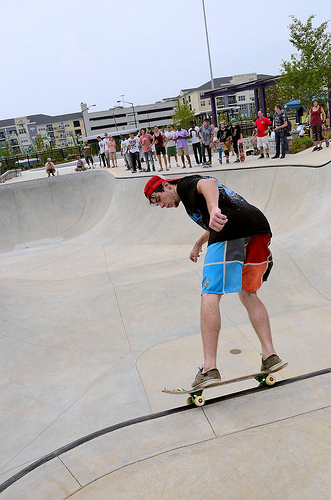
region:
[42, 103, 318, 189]
many people watching skateboarder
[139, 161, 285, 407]
man skateboarding at skateboard park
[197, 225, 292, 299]
man wearing shorts with a square pattern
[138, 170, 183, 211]
man wearing a red baseball cap baskwards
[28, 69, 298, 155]
buildings in the background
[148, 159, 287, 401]
skateboarder doing a trick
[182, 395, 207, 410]
white wheels of skateboard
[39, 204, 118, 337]
gre cement of skateboarding park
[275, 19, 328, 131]
trees with green leaves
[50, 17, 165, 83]
clear bright blue skies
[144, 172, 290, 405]
a man skateboarding on a rail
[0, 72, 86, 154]
tall apartment buildings in the background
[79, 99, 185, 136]
a large multi-level parking structure in the background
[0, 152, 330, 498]
a skateboard park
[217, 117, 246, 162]
two skateboarders watching the man skateboarding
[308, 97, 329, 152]
a skateboarder wearing a helmut and a red tanktop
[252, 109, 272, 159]
a man wearing a bright red shirt and off white shorts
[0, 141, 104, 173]
a black metal fence at the back of the skatepark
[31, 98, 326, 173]
a group of onlookers watching the man skateboard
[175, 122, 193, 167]
a man wearing a lavender shirt and khaki shorts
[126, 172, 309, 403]
Man on a skateboard.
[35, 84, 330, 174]
Spectators watching the man.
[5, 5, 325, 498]
The picture was taken at a skate park.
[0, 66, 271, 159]
Buildings in the background.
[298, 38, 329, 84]
The tree is green.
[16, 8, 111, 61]
The sky is blue.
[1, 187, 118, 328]
The equipment is made of cement.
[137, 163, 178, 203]
The man is wearing a hat.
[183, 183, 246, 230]
The shirt is mostly black.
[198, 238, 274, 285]
The shorts are multicolored.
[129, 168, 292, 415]
the man is skateboarding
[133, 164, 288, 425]
the man is trying to keep balance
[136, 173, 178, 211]
the man's hat is red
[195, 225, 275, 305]
the man's shorts are 4 different colors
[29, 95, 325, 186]
people are watching the skateboarder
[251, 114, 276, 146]
man's shirt is red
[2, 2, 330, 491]
the people are at a skatepark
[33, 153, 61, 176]
the man is squatting down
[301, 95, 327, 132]
the person is wearing a tank top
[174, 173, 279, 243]
the man's shirt is black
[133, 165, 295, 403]
The man is skateboarding.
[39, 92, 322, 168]
People are watching the man skateboard.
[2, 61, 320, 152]
Buildings in the distance.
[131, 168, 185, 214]
The man is wearing a red hat.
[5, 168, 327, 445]
The skateboarding area is made out of concrete.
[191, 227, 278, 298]
The man is wearing shorts.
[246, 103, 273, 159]
The man is wearing a red t-shirt.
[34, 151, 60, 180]
The person is crouching down.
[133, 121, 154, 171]
The person is standing up.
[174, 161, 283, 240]
The skateboarder is wearing a black shirt.